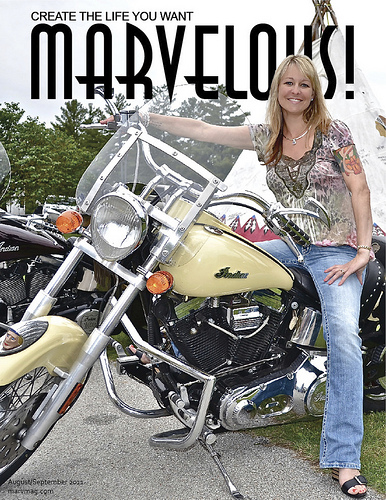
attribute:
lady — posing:
[133, 48, 374, 409]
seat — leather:
[268, 247, 371, 317]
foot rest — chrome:
[142, 342, 328, 432]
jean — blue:
[264, 236, 377, 451]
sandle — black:
[327, 465, 381, 497]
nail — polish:
[348, 469, 374, 494]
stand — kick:
[177, 415, 272, 496]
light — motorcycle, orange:
[142, 245, 201, 293]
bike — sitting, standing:
[1, 127, 319, 498]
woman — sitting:
[205, 66, 376, 300]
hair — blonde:
[290, 52, 322, 64]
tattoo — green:
[310, 143, 369, 210]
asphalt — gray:
[44, 418, 107, 490]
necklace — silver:
[264, 114, 319, 162]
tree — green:
[0, 90, 123, 204]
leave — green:
[60, 103, 104, 154]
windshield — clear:
[63, 96, 227, 268]